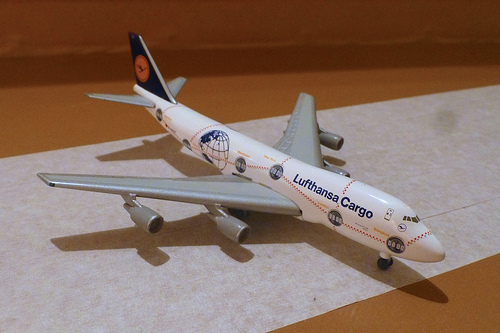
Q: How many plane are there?
A: One.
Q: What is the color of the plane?
A: White, blue.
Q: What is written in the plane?
A: Lufthansa cargo.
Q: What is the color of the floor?
A: Brown and white.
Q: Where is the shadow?
A: In the floor.